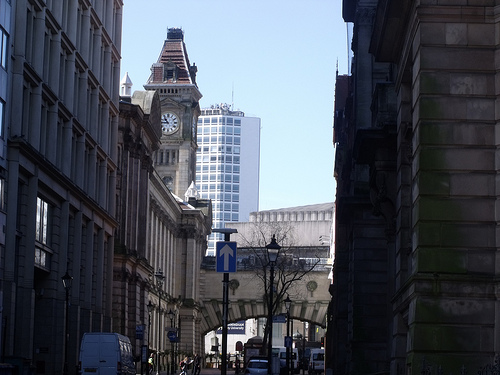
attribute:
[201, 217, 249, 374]
post — black, tall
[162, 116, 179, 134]
hands — black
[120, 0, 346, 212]
sky — blue 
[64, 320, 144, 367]
van — white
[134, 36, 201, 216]
building — tall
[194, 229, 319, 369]
streetlight — old-fashioned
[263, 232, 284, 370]
lamp post — tall, black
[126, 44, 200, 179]
tower — clock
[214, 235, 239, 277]
sign — blue and white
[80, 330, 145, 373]
van — white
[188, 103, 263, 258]
building — tall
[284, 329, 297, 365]
van — white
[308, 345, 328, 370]
van — white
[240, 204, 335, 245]
building — grey, low-roofed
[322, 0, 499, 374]
building — weathered, brick, elderly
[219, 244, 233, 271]
arrow — white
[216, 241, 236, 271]
background — blue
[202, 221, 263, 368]
pole — black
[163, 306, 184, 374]
lamp post — tall, black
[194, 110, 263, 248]
highrise — modern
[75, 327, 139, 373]
van — white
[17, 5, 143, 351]
building — huge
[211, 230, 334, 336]
overhang — cement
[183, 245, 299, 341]
carving — intricate